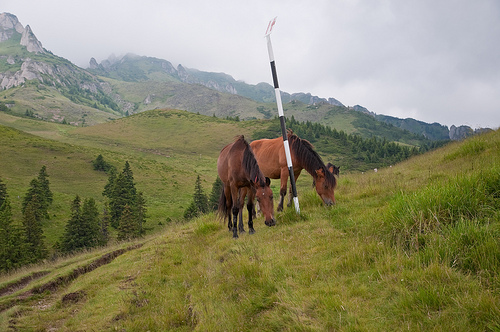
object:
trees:
[360, 134, 401, 162]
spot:
[258, 182, 274, 204]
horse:
[247, 127, 342, 213]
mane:
[288, 132, 337, 182]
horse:
[213, 134, 278, 240]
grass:
[0, 116, 77, 144]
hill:
[0, 126, 226, 272]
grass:
[81, 228, 260, 313]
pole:
[264, 16, 301, 213]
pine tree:
[115, 190, 149, 243]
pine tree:
[106, 158, 138, 228]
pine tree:
[20, 165, 55, 220]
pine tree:
[51, 194, 109, 251]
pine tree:
[20, 193, 49, 263]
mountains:
[383, 113, 499, 148]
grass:
[303, 254, 353, 295]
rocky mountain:
[0, 11, 92, 95]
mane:
[245, 151, 265, 184]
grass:
[394, 133, 499, 231]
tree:
[205, 176, 223, 211]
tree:
[183, 172, 214, 221]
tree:
[90, 152, 117, 172]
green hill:
[71, 107, 263, 153]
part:
[371, 231, 419, 253]